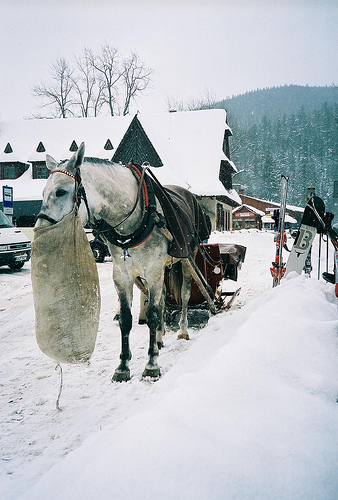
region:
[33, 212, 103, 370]
sack over horse mouth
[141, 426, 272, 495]
cold wet snow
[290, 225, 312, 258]
a large silver letter on a snowboard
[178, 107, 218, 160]
snow on a roof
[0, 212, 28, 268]
a white van parked nearby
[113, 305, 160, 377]
blackened knees of a horse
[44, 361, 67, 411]
a string hanging from the sack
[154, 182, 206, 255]
a black blanket over th horse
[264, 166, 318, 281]
snowboards stuck in the snow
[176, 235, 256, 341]
a brown sleigh behind th horse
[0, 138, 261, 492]
Horse on the street on a snowy day.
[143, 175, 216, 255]
Horseback covered with black horse blanket.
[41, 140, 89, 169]
Horse ears are pointing up.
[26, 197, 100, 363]
Horse food bag hanging under the neck while eating.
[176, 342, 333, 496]
Piled up snow on the street side.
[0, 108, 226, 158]
Roof fully covered of snow.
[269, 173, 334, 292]
Skis standing in the snow.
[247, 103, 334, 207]
Very tall pin trees in the background.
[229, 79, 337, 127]
Very high mountains in the background.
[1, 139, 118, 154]
Roof with small triangular designs.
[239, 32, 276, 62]
grey cloudy skies over the scene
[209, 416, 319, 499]
smooth white surface of the snow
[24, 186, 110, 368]
a feed bag on a horse's head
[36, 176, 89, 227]
black leather bridle on the horse's head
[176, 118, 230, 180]
white snow on the roof of a building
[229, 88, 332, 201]
snow covered trees in the distance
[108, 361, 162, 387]
the black hooves of the horse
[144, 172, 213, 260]
brown blanket over the horse's back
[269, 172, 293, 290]
a pair of skis planted in the ground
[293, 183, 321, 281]
a black and white snowboard leaning on a rack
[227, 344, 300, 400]
this is the ground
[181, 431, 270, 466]
the ground is full of snow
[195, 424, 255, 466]
the snow is white in color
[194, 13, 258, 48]
this is the sky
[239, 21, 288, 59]
the sky has clouds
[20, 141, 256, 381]
this is a horse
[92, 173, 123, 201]
the fur is white in color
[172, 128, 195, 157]
this is a roof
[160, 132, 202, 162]
the roof has snow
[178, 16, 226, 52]
this is the sky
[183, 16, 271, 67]
the sky has clouds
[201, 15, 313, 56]
the clouds are white in color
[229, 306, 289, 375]
this is the ground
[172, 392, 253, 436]
the ground has snow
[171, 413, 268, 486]
the snow is white in color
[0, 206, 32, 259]
this is a car